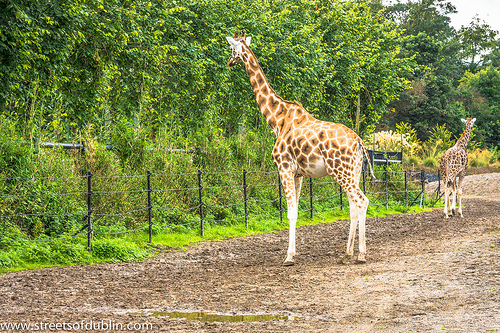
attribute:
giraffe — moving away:
[436, 113, 476, 220]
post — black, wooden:
[438, 167, 441, 206]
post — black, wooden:
[418, 168, 425, 207]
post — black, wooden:
[401, 171, 409, 208]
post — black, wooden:
[383, 172, 391, 209]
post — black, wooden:
[360, 170, 367, 210]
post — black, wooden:
[336, 181, 344, 211]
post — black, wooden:
[305, 172, 315, 216]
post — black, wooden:
[276, 168, 288, 229]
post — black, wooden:
[241, 168, 251, 228]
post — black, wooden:
[195, 168, 207, 238]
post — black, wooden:
[143, 170, 155, 242]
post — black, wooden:
[83, 170, 93, 248]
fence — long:
[18, 142, 444, 264]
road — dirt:
[128, 220, 499, 332]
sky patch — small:
[448, 26, 498, 69]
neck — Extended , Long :
[243, 51, 302, 123]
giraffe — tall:
[216, 27, 386, 275]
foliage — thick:
[18, 16, 193, 153]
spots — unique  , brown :
[265, 114, 347, 165]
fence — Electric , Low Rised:
[20, 171, 450, 218]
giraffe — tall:
[221, 42, 416, 313]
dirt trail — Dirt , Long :
[0, 200, 492, 331]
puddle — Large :
[126, 298, 298, 330]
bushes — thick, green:
[6, 98, 493, 251]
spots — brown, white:
[291, 140, 355, 180]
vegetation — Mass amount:
[1, 118, 420, 258]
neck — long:
[239, 53, 278, 125]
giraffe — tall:
[429, 101, 483, 227]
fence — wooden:
[41, 116, 474, 279]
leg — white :
[355, 197, 375, 258]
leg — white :
[341, 195, 363, 252]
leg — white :
[283, 197, 302, 265]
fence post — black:
[307, 175, 317, 220]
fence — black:
[30, 95, 335, 257]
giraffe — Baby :
[432, 117, 477, 227]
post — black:
[82, 171, 96, 249]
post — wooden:
[191, 173, 212, 238]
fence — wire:
[0, 165, 440, 265]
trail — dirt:
[6, 173, 496, 330]